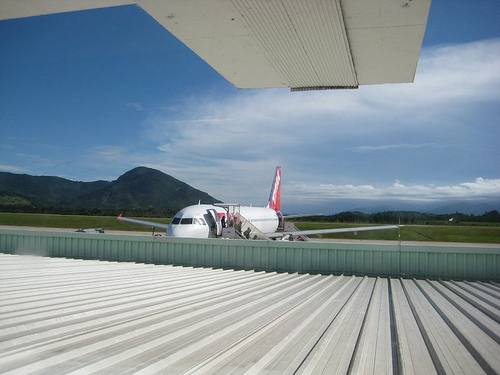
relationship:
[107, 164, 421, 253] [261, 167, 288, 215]
tail fin of plane